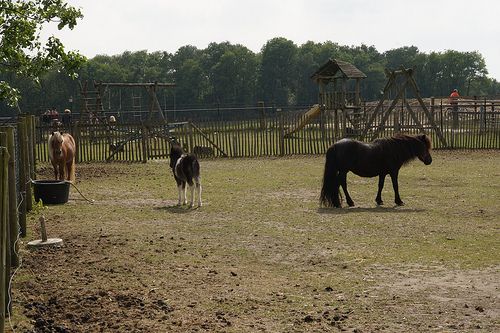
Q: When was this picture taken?
A: During the day.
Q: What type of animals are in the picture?
A: Horses.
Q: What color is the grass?
A: Green.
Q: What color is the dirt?
A: Brown.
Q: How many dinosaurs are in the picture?
A: Zero.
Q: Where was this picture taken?
A: Horse pasture.